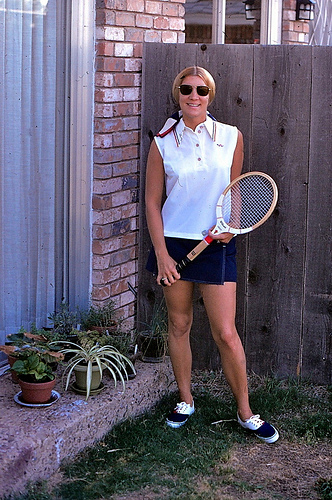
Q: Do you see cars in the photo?
A: No, there are no cars.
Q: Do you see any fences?
A: Yes, there is a fence.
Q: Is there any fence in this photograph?
A: Yes, there is a fence.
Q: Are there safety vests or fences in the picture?
A: Yes, there is a fence.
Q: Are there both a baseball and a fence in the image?
A: No, there is a fence but no baseballs.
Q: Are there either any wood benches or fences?
A: Yes, there is a wood fence.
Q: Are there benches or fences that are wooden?
A: Yes, the fence is wooden.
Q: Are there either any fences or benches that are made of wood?
A: Yes, the fence is made of wood.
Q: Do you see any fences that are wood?
A: Yes, there is a wood fence.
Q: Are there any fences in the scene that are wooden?
A: Yes, there is a fence that is wooden.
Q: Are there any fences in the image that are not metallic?
A: Yes, there is a wooden fence.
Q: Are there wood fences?
A: Yes, there is a fence that is made of wood.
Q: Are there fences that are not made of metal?
A: Yes, there is a fence that is made of wood.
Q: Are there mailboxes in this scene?
A: No, there are no mailboxes.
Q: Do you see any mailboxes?
A: No, there are no mailboxes.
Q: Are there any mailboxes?
A: No, there are no mailboxes.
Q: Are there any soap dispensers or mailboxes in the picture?
A: No, there are no mailboxes or soap dispensers.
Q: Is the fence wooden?
A: Yes, the fence is wooden.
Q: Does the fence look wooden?
A: Yes, the fence is wooden.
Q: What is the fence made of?
A: The fence is made of wood.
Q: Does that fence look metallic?
A: No, the fence is wooden.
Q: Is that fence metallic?
A: No, the fence is wooden.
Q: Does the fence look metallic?
A: No, the fence is wooden.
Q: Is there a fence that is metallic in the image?
A: No, there is a fence but it is wooden.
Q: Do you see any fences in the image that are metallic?
A: No, there is a fence but it is wooden.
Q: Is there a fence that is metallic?
A: No, there is a fence but it is wooden.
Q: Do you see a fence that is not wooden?
A: No, there is a fence but it is wooden.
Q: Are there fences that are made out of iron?
A: No, there is a fence but it is made of wood.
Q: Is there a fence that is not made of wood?
A: No, there is a fence but it is made of wood.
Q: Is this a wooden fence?
A: Yes, this is a wooden fence.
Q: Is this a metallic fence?
A: No, this is a wooden fence.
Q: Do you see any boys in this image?
A: No, there are no boys.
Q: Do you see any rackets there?
A: Yes, there is a racket.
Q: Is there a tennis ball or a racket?
A: Yes, there is a racket.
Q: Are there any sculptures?
A: No, there are no sculptures.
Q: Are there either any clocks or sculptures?
A: No, there are no sculptures or clocks.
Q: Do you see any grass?
A: Yes, there is grass.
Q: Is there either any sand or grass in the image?
A: Yes, there is grass.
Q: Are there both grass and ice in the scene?
A: No, there is grass but no ice.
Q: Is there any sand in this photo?
A: No, there is no sand.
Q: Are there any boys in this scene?
A: No, there are no boys.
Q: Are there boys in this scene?
A: No, there are no boys.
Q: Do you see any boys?
A: No, there are no boys.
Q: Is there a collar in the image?
A: Yes, there is a collar.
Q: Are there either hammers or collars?
A: Yes, there is a collar.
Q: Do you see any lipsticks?
A: No, there are no lipsticks.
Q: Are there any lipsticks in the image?
A: No, there are no lipsticks.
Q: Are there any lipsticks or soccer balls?
A: No, there are no lipsticks or soccer balls.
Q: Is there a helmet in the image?
A: No, there are no helmets.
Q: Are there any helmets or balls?
A: No, there are no helmets or balls.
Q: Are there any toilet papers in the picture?
A: No, there are no toilet papers.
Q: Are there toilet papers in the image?
A: No, there are no toilet papers.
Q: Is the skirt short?
A: Yes, the skirt is short.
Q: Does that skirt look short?
A: Yes, the skirt is short.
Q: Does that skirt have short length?
A: Yes, the skirt is short.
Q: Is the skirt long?
A: No, the skirt is short.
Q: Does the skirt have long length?
A: No, the skirt is short.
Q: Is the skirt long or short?
A: The skirt is short.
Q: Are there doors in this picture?
A: Yes, there is a door.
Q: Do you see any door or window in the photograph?
A: Yes, there is a door.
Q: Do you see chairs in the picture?
A: No, there are no chairs.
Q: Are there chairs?
A: No, there are no chairs.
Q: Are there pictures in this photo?
A: No, there are no pictures.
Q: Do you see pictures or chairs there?
A: No, there are no pictures or chairs.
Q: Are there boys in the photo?
A: No, there are no boys.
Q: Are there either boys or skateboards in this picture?
A: No, there are no boys or skateboards.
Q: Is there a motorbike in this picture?
A: No, there are no motorcycles.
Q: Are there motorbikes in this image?
A: No, there are no motorbikes.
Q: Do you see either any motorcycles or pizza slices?
A: No, there are no motorcycles or pizza slices.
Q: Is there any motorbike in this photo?
A: No, there are no motorcycles.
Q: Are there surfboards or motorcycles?
A: No, there are no motorcycles or surfboards.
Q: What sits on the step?
A: The plants sit on the step.